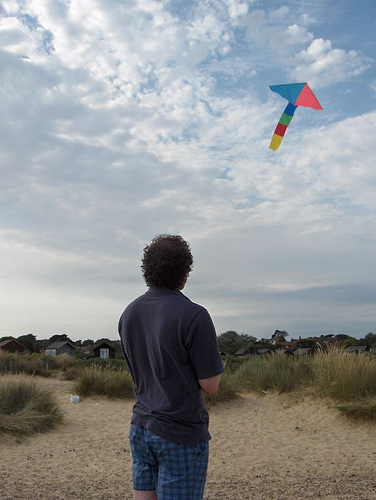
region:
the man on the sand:
[118, 233, 223, 498]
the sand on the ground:
[0, 363, 374, 498]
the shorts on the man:
[128, 421, 209, 498]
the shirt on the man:
[117, 287, 223, 444]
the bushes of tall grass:
[1, 339, 375, 443]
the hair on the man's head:
[141, 231, 194, 289]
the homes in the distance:
[0, 335, 374, 350]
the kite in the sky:
[268, 82, 323, 150]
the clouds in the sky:
[0, 0, 375, 342]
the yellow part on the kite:
[268, 132, 283, 150]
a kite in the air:
[254, 69, 331, 163]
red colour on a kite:
[275, 122, 287, 137]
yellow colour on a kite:
[267, 133, 280, 148]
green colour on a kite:
[279, 114, 291, 125]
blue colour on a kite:
[286, 103, 296, 112]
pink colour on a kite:
[301, 85, 320, 110]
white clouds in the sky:
[41, 0, 139, 72]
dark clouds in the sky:
[10, 92, 110, 246]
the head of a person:
[136, 235, 191, 288]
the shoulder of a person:
[176, 295, 215, 342]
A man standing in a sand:
[110, 216, 227, 493]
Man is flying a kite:
[81, 55, 365, 376]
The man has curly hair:
[68, 224, 225, 493]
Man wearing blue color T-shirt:
[94, 221, 229, 498]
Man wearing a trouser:
[62, 221, 229, 496]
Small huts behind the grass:
[3, 327, 117, 373]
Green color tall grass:
[234, 342, 364, 405]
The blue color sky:
[25, 160, 207, 222]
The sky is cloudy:
[52, 165, 351, 229]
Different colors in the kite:
[241, 61, 347, 161]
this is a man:
[111, 228, 231, 476]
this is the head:
[141, 237, 192, 282]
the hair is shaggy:
[142, 242, 192, 279]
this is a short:
[126, 438, 211, 489]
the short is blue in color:
[160, 446, 205, 492]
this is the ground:
[257, 424, 333, 484]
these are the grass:
[316, 349, 370, 388]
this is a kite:
[251, 83, 321, 150]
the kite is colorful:
[256, 77, 331, 151]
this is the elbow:
[198, 374, 221, 394]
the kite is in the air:
[261, 73, 323, 154]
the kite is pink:
[302, 94, 311, 103]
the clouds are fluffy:
[109, 28, 158, 61]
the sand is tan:
[297, 441, 348, 478]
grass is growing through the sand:
[98, 390, 122, 405]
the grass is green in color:
[250, 365, 273, 378]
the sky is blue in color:
[341, 7, 360, 41]